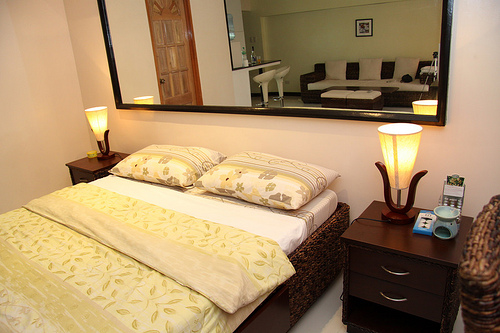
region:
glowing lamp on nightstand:
[362, 119, 435, 230]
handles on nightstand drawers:
[372, 259, 414, 306]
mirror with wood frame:
[95, 11, 470, 125]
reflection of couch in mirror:
[295, 49, 437, 106]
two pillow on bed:
[117, 135, 335, 207]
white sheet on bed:
[203, 197, 275, 232]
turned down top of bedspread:
[34, 236, 261, 313]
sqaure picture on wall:
[343, 11, 380, 45]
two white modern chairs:
[252, 60, 294, 105]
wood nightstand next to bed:
[318, 196, 480, 317]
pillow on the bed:
[206, 146, 333, 227]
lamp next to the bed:
[345, 121, 436, 222]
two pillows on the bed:
[134, 131, 316, 204]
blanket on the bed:
[37, 193, 211, 280]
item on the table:
[420, 195, 470, 237]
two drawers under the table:
[348, 264, 428, 316]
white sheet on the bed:
[223, 207, 249, 223]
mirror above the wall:
[228, 10, 335, 64]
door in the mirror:
[128, 27, 209, 96]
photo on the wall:
[337, 8, 390, 53]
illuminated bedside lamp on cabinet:
[351, 105, 453, 200]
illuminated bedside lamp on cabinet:
[75, 87, 140, 193]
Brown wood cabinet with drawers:
[356, 189, 498, 304]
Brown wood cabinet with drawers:
[77, 145, 143, 192]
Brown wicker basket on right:
[463, 200, 497, 286]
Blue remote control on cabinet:
[408, 201, 440, 236]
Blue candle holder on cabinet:
[421, 202, 461, 251]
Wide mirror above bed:
[90, 2, 445, 122]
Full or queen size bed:
[21, 141, 305, 330]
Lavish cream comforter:
[10, 160, 192, 326]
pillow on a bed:
[188, 138, 343, 210]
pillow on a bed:
[104, 131, 232, 188]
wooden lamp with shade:
[362, 116, 434, 232]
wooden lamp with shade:
[82, 101, 117, 163]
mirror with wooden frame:
[90, 0, 464, 132]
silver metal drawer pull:
[377, 261, 415, 279]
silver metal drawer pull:
[373, 288, 415, 305]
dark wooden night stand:
[332, 189, 484, 331]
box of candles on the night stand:
[406, 200, 441, 235]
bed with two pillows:
[0, 138, 358, 332]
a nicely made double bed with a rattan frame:
[10, 143, 347, 325]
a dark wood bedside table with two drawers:
[342, 220, 467, 332]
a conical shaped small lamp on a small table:
[76, 105, 118, 157]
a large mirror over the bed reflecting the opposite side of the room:
[89, 6, 471, 133]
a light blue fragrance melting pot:
[429, 206, 460, 240]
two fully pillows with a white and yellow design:
[115, 142, 338, 209]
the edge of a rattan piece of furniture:
[459, 206, 499, 329]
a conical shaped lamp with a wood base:
[357, 117, 427, 224]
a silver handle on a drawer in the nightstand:
[377, 261, 412, 278]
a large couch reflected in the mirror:
[299, 58, 436, 103]